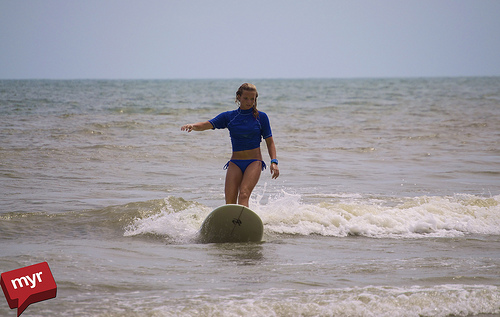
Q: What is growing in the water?
A: Waves.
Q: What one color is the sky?
A: Blue.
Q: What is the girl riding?
A: A surfboard.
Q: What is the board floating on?
A: The water.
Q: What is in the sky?
A: Nothing.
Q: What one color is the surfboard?
A: White.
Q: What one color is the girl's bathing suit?
A: Blue.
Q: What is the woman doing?
A: Surfing.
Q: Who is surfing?
A: A woman.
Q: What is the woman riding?
A: A surfboard.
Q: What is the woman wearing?
A: Blue bikini bottoms.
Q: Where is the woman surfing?
A: The ocean.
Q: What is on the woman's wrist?
A: Blue bracelet.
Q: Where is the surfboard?
A: Under the woman.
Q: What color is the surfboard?
A: White.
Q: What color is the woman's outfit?
A: Blue.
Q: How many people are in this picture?
A: One.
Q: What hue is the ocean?
A: Blue.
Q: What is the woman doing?
A: Surfing.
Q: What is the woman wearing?
A: Blue bikini.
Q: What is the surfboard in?
A: Water.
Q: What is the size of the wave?
A: Small.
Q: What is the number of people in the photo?
A: One.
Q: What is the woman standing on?
A: Surfboard.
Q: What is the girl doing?
A: Surfing.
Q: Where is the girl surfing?
A: The beach.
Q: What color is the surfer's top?
A: Blue.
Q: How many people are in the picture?
A: 1.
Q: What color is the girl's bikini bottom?
A: Blue.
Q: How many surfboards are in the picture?
A: 1.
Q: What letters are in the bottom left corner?
A: Myr.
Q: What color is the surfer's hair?
A: Blonde.